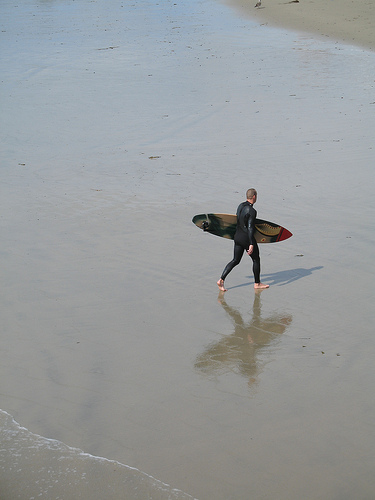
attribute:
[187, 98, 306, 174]
water — colourless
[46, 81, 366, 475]
sand — wet  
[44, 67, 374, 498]
sand — wet  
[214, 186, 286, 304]
wetsuit — black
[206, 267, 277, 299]
feet — bare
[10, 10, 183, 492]
sand — wet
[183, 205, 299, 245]
surfboard — yellow, black , red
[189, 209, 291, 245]
surfboard — multicolored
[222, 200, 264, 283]
suit — wet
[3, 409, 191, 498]
water — colorless, shallow, ocean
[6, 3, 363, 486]
area — large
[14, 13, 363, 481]
sand — wet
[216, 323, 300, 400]
water — clear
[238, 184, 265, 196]
head — wet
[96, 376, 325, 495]
water — colorless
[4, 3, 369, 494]
water — calm